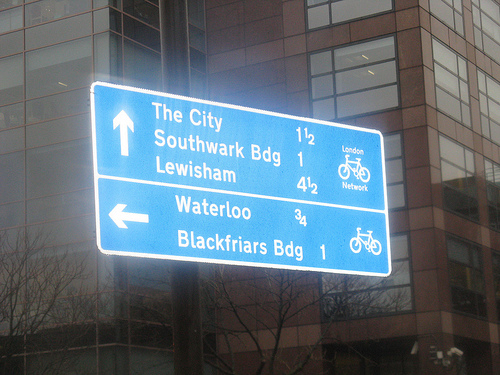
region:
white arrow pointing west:
[118, 203, 136, 248]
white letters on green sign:
[178, 192, 266, 224]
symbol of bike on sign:
[345, 228, 404, 266]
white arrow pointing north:
[112, 111, 139, 162]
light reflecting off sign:
[99, 100, 414, 294]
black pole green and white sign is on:
[165, 260, 193, 372]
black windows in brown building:
[441, 141, 492, 232]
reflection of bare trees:
[8, 284, 73, 314]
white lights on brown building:
[412, 335, 471, 373]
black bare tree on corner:
[218, 275, 296, 373]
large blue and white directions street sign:
[87, 79, 392, 279]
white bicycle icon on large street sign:
[338, 153, 371, 182]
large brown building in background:
[203, 0, 499, 374]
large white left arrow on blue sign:
[109, 203, 149, 230]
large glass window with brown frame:
[307, 36, 402, 121]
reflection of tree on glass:
[1, 228, 87, 348]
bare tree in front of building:
[173, 269, 370, 371]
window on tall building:
[438, 136, 481, 221]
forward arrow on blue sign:
[111, 107, 136, 157]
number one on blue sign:
[318, 241, 330, 261]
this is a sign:
[84, 83, 409, 283]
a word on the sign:
[267, 231, 303, 277]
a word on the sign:
[161, 195, 262, 227]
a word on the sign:
[173, 220, 265, 256]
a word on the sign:
[133, 153, 240, 201]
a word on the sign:
[146, 127, 246, 169]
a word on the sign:
[241, 142, 278, 168]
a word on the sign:
[147, 83, 189, 128]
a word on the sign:
[185, 106, 230, 136]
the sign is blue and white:
[65, 40, 436, 311]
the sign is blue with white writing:
[77, 80, 465, 367]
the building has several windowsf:
[12, 20, 100, 182]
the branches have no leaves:
[198, 278, 345, 331]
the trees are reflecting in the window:
[12, 214, 100, 364]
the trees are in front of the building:
[7, 232, 257, 337]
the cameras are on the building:
[400, 332, 483, 373]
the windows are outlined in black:
[300, 290, 437, 357]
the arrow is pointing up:
[95, 95, 148, 178]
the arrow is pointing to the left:
[87, 180, 163, 239]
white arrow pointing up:
[101, 97, 139, 159]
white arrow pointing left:
[117, 203, 150, 234]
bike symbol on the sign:
[343, 222, 388, 278]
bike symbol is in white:
[341, 219, 386, 261]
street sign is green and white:
[86, 73, 411, 301]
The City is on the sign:
[150, 95, 225, 135]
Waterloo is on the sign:
[173, 195, 262, 232]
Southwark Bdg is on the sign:
[154, 126, 292, 173]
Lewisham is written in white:
[151, 151, 240, 187]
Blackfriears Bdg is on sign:
[164, 222, 309, 265]